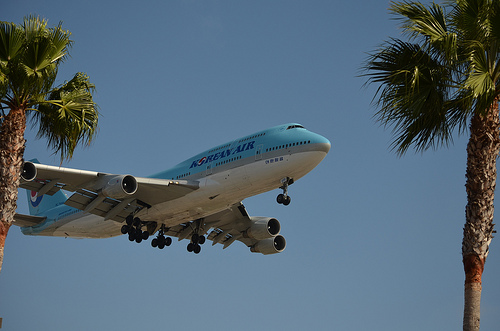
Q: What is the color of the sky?
A: Blue.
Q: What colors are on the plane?
A: Blue and white.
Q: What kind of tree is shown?
A: A palm tree.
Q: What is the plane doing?
A: Flying.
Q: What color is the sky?
A: Blue.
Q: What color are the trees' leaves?
A: Green.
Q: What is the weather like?
A: Sunny.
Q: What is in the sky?
A: The airplane.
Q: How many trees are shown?
A: Two.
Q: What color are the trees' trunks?
A: Brown.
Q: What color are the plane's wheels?
A: Black.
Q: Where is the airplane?
A: In the air.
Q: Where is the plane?
A: Sky.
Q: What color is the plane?
A: Blue and white.